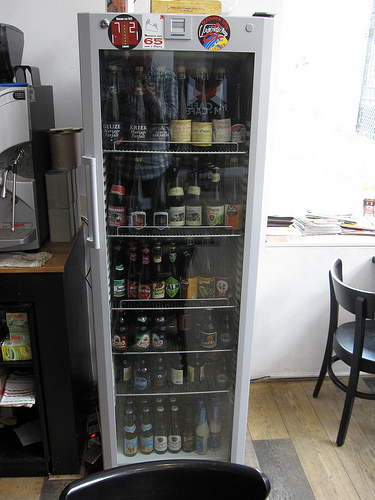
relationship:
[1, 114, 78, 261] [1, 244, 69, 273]
machine on top of counter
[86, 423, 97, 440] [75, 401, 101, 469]
light attached to outlet